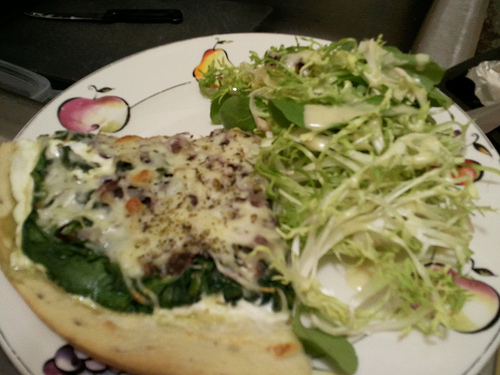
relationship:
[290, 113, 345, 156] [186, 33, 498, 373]
dressing on salad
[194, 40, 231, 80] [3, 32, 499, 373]
pear on plate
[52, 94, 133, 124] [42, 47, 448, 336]
apple on plate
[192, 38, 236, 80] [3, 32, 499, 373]
pear design painted plate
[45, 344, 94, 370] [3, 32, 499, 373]
grape image on plate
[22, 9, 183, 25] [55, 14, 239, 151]
knife on plate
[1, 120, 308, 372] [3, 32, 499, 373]
pizza on plate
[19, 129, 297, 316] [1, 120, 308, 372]
spinach on pizza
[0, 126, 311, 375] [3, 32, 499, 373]
pizza on plate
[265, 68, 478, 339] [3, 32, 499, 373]
vegetable sprouts on plate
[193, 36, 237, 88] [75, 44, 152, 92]
pear on plate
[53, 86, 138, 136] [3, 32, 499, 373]
apple design on plate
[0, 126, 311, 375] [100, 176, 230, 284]
pizza with spinach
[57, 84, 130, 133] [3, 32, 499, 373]
apple on plate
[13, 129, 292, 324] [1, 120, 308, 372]
cheese on pizza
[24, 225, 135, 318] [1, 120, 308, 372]
spinach on top of pizza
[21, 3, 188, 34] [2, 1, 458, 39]
knife in background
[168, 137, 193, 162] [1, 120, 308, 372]
meat on pizza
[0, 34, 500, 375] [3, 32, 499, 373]
salad on plate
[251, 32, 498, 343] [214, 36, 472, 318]
dressing on salad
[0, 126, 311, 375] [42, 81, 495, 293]
pizza on plate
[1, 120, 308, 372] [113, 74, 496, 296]
pizza on plate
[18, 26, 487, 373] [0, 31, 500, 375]
salad on plate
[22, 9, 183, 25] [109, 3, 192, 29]
knife has black handle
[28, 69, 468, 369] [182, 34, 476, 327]
plate has food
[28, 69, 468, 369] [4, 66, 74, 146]
plate on table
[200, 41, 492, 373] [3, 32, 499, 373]
sprouts on plate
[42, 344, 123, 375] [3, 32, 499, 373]
grape image on plate